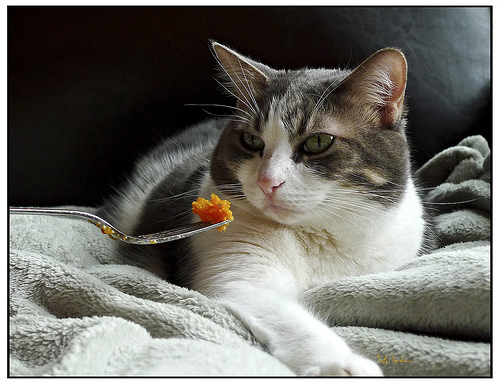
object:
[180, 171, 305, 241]
fed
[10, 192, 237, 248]
fork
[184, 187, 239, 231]
food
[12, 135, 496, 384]
blanket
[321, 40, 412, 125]
ear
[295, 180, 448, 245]
whiskers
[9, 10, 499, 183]
couch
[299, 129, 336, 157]
eye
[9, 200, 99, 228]
handle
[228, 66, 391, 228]
face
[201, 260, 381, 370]
arm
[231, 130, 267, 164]
eye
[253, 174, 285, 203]
nose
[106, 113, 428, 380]
body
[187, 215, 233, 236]
tip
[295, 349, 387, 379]
paw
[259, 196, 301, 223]
mouth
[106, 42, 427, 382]
cat